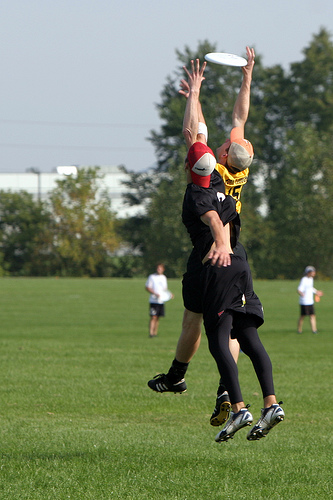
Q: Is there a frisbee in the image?
A: Yes, there is a frisbee.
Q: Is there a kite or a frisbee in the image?
A: Yes, there is a frisbee.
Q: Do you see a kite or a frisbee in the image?
A: Yes, there is a frisbee.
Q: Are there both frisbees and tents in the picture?
A: No, there is a frisbee but no tents.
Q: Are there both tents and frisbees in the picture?
A: No, there is a frisbee but no tents.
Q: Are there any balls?
A: No, there are no balls.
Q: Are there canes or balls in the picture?
A: No, there are no balls or canes.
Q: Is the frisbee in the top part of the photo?
A: Yes, the frisbee is in the top of the image.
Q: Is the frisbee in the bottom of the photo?
A: No, the frisbee is in the top of the image.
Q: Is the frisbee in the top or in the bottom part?
A: The frisbee is in the top of the image.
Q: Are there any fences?
A: No, there are no fences.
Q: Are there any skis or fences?
A: No, there are no fences or skis.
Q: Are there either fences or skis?
A: No, there are no fences or skis.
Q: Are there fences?
A: No, there are no fences.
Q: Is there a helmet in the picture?
A: No, there are no helmets.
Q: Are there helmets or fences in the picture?
A: No, there are no helmets or fences.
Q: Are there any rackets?
A: No, there are no rackets.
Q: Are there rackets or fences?
A: No, there are no rackets or fences.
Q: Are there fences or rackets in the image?
A: No, there are no rackets or fences.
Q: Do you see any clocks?
A: No, there are no clocks.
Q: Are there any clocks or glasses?
A: No, there are no clocks or glasses.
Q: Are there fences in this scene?
A: No, there are no fences.